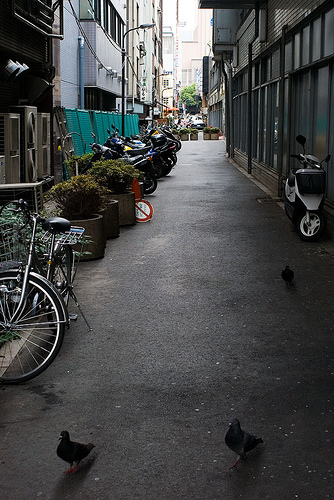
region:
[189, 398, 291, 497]
a dove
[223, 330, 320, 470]
a dove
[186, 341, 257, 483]
a dove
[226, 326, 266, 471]
a dove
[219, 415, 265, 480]
a dove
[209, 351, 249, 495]
a dove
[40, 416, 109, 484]
dark grey bird with pink and orange feet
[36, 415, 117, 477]
dark grey pigeon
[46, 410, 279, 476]
two pigeons walking on the ground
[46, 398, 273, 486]
two pigeons with beaks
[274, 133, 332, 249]
black and white motorcycle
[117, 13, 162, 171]
tall metal light pole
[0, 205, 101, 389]
black bicycle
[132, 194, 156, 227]
red and white prohibiting sign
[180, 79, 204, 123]
tall green tree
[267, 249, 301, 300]
pigeon walking toward alley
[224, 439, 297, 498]
a dove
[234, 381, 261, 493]
a dove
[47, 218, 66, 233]
seat of the bicycle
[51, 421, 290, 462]
birds on the ground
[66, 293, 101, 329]
kick stand on the bike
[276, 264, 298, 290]
a black bird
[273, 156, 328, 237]
a moped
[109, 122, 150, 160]
motorcycles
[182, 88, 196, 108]
leaves on the tree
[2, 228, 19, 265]
backet on the bicycle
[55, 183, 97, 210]
a green bush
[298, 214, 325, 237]
front tire on moped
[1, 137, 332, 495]
paved urban alley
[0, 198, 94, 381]
parked bicycle with wire basket in front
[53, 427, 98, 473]
pigeon standing on asphalt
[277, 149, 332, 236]
parked white scooter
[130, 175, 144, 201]
orange traffic cone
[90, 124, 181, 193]
row of parked scooters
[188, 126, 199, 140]
concrete planter box at end of alley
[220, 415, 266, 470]
pigeon standing on asphalt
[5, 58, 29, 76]
three metal exhaust pipes mounted on wall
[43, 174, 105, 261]
shrub in wood barrel planter